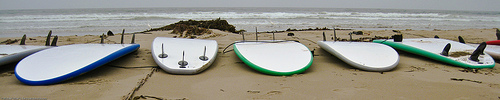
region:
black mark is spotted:
[456, 75, 470, 97]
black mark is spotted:
[464, 68, 469, 92]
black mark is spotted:
[449, 57, 465, 87]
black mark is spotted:
[456, 75, 460, 85]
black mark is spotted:
[449, 72, 460, 94]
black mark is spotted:
[456, 75, 458, 85]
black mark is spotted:
[454, 69, 464, 91]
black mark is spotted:
[454, 76, 459, 97]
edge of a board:
[263, 48, 296, 78]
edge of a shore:
[324, 2, 355, 26]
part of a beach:
[223, 73, 246, 95]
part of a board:
[256, 35, 287, 88]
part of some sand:
[232, 74, 248, 89]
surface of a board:
[258, 43, 280, 73]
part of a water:
[373, 0, 417, 23]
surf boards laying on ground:
[21, 8, 424, 89]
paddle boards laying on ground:
[31, 16, 306, 97]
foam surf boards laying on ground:
[70, 12, 435, 97]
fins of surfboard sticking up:
[151, 42, 226, 82]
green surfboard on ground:
[261, 14, 326, 95]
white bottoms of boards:
[51, 21, 424, 98]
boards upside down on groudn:
[14, 8, 411, 98]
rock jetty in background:
[158, 12, 237, 44]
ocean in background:
[12, 3, 306, 54]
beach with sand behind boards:
[12, 23, 224, 83]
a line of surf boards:
[3, 34, 498, 85]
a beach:
[8, 37, 485, 99]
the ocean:
[4, 4, 499, 34]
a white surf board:
[313, 31, 400, 87]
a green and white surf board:
[233, 19, 313, 76]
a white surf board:
[142, 25, 222, 81]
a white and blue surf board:
[19, 39, 141, 96]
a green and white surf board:
[379, 25, 484, 76]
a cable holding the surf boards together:
[5, 37, 498, 68]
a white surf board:
[0, 32, 65, 68]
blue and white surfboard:
[23, 37, 136, 84]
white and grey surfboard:
[151, 22, 208, 86]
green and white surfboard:
[228, 30, 319, 94]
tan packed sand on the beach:
[48, 30, 486, 98]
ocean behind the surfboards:
[76, 8, 492, 35]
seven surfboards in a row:
[6, 35, 497, 81]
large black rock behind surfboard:
[162, 10, 253, 42]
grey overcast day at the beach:
[6, 0, 498, 36]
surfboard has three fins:
[146, 30, 238, 82]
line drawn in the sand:
[115, 56, 177, 98]